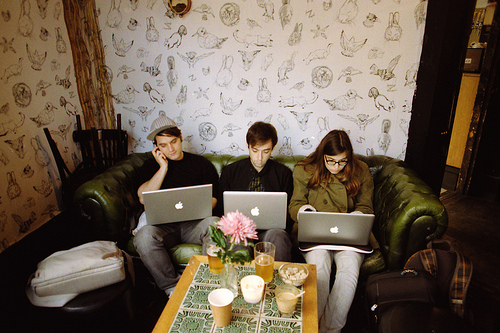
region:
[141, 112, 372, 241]
three people on couch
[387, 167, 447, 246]
arm of the couch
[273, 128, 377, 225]
girl in the photo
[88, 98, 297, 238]
two men in the photo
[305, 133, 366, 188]
head of the girl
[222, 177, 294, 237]
apple laptop in photo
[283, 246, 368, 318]
white pants on girl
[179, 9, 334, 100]
wall behind the people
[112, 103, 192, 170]
hat on man's head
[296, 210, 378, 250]
grey laptop on her lap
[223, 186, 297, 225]
apple laptop on lap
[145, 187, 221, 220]
gray macbook on lap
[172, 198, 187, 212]
apple logo on monitor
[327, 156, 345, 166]
glasses on the woman's face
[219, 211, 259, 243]
pink flower on table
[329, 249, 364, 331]
the woman's left leg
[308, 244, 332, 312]
the woman's right leg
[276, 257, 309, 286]
bowl on the table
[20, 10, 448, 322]
Three people on laptops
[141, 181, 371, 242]
Three silver laptops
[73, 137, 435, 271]
A green colored sofa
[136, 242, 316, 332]
A yellow table with green center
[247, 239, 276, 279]
A glass with yellow liquid in it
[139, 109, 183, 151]
A grey baseball cap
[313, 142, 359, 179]
A pair of brown rimmed glasses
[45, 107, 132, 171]
A dark brown chair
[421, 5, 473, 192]
A dark brown doorway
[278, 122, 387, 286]
the woman on the couch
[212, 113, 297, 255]
the man on the couch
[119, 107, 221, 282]
the man on the couch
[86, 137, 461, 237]
the couch is green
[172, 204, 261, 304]
the flower in the vase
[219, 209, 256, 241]
the flower is pink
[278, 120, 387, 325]
the woman using the laptop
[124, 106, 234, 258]
the man on the phone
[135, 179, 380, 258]
three open laptops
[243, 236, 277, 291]
glass of yellow liquid on table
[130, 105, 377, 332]
three people sitting on couch next to each other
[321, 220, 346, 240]
white apple on front of silver computers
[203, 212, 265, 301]
pink flower in vase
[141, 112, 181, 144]
baseball cap on man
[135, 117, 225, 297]
man on cell phone and holding laptop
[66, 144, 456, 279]
green leather sofa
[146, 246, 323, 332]
wooden coffee table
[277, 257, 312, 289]
bowl of chips on table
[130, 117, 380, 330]
Three people sitting on a sofa looking at laptops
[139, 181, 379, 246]
Three laptops that are open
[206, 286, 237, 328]
Plastic cup sitting on a table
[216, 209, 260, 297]
Flower in a vase sitting on a table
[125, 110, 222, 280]
man in a black shirt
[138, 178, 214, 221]
apple macbook pro laptop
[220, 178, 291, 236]
silver and white colored laptop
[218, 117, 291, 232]
asian man wearing a black shirt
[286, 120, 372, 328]
woman in a green jacket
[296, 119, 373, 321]
woman with glasses holding laptop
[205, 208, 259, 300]
huge rose in middle of table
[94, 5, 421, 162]
wall with sketched designs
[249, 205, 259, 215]
apple logo on macbook pro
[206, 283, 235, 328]
coffee cup on table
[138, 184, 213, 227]
an open MacBook laptop computer